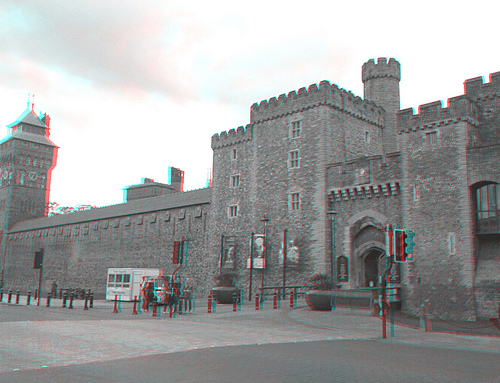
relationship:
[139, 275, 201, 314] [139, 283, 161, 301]
people wearing black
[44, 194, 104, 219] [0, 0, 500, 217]
trees against sky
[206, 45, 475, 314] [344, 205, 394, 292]
building has entrance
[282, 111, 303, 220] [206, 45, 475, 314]
windows on building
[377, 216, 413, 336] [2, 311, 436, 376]
traffic light along road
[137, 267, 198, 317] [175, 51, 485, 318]
people front building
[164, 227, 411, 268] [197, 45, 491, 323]
traffic lights front castle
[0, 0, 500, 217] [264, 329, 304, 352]
sky seen part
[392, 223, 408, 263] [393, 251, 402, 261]
traffic light seen part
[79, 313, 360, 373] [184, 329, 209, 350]
walking path has part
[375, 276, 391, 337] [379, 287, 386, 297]
post seen part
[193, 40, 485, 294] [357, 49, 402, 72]
castle has tip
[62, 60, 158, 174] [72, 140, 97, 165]
sky seen part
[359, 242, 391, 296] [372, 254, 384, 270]
entrance seen section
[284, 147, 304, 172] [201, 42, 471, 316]
window in castle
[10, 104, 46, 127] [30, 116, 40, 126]
roof seen part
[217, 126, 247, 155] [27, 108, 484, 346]
sign on building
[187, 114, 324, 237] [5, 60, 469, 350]
windows on building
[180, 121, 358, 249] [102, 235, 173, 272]
windows on wall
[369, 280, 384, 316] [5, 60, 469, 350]
man walking side building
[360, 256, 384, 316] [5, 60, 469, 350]
man beside building